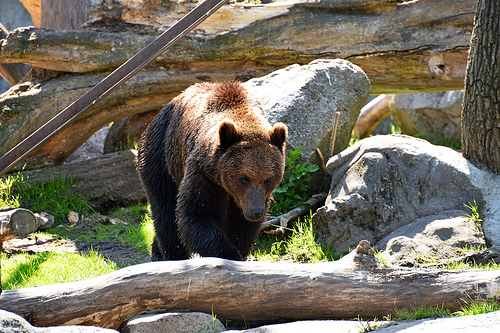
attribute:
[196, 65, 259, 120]
fur — brown 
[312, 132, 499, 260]
rock — big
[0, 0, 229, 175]
railing — metal 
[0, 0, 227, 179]
bar — metal 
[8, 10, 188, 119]
bar — iron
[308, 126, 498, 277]
boulder — large 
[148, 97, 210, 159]
fur — brown 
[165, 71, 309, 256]
bear — brown 